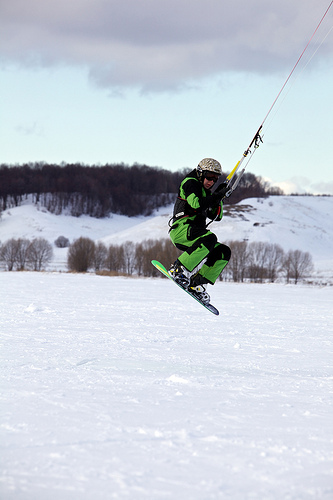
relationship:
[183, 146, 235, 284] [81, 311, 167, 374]
girl on snow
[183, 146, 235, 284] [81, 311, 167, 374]
girl in snow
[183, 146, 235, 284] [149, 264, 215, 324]
girl on board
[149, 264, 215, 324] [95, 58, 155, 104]
board in sky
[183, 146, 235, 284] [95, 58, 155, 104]
girl in sky